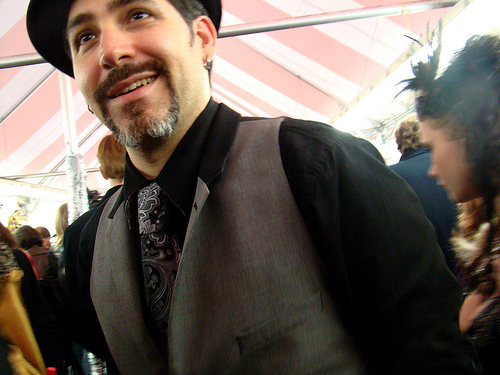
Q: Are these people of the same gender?
A: No, they are both male and female.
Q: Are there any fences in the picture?
A: No, there are no fences.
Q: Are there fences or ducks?
A: No, there are no fences or ducks.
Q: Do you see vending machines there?
A: No, there are no vending machines.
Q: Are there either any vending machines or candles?
A: No, there are no vending machines or candles.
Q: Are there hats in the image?
A: Yes, there is a hat.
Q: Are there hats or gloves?
A: Yes, there is a hat.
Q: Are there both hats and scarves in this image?
A: No, there is a hat but no scarves.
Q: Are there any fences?
A: No, there are no fences.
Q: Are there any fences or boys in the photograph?
A: No, there are no fences or boys.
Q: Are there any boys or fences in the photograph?
A: No, there are no fences or boys.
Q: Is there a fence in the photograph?
A: No, there are no fences.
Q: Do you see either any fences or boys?
A: No, there are no fences or boys.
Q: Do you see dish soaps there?
A: No, there are no dish soaps.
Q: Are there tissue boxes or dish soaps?
A: No, there are no dish soaps or tissue boxes.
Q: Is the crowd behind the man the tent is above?
A: Yes, the crowd is behind the man.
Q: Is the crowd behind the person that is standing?
A: Yes, the crowd is behind the man.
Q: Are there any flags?
A: No, there are no flags.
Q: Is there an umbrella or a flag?
A: No, there are no flags or umbrellas.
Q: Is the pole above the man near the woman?
A: Yes, the pole is above the man.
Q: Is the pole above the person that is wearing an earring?
A: Yes, the pole is above the man.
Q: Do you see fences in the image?
A: No, there are no fences.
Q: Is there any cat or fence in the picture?
A: No, there are no fences or cats.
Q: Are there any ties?
A: Yes, there is a tie.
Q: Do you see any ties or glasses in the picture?
A: Yes, there is a tie.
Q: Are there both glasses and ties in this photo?
A: No, there is a tie but no glasses.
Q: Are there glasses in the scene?
A: No, there are no glasses.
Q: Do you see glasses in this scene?
A: No, there are no glasses.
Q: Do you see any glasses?
A: No, there are no glasses.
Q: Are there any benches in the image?
A: No, there are no benches.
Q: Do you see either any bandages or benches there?
A: No, there are no benches or bandages.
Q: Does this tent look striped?
A: Yes, the tent is striped.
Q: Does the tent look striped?
A: Yes, the tent is striped.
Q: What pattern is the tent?
A: The tent is striped.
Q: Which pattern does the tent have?
A: The tent has striped pattern.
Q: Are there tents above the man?
A: Yes, there is a tent above the man.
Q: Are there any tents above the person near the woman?
A: Yes, there is a tent above the man.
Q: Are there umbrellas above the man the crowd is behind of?
A: No, there is a tent above the man.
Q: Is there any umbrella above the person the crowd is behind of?
A: No, there is a tent above the man.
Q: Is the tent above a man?
A: Yes, the tent is above a man.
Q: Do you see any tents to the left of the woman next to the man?
A: Yes, there is a tent to the left of the woman.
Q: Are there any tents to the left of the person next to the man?
A: Yes, there is a tent to the left of the woman.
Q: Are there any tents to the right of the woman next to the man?
A: No, the tent is to the left of the woman.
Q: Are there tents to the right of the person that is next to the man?
A: No, the tent is to the left of the woman.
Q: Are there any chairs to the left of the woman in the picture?
A: No, there is a tent to the left of the woman.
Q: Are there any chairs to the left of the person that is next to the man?
A: No, there is a tent to the left of the woman.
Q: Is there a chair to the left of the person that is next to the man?
A: No, there is a tent to the left of the woman.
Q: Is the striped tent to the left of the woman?
A: Yes, the tent is to the left of the woman.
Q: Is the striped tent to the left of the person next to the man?
A: Yes, the tent is to the left of the woman.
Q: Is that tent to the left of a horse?
A: No, the tent is to the left of the woman.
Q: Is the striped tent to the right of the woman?
A: No, the tent is to the left of the woman.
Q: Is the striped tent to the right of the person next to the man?
A: No, the tent is to the left of the woman.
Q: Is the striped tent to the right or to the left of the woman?
A: The tent is to the left of the woman.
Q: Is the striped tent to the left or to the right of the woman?
A: The tent is to the left of the woman.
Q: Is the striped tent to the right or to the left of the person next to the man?
A: The tent is to the left of the woman.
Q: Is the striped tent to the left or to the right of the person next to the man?
A: The tent is to the left of the woman.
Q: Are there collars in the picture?
A: Yes, there is a collar.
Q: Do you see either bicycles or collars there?
A: Yes, there is a collar.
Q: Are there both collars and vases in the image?
A: No, there is a collar but no vases.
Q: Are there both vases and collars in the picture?
A: No, there is a collar but no vases.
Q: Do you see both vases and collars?
A: No, there is a collar but no vases.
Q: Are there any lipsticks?
A: No, there are no lipsticks.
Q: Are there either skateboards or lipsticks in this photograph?
A: No, there are no lipsticks or skateboards.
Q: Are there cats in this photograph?
A: No, there are no cats.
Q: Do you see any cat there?
A: No, there are no cats.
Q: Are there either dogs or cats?
A: No, there are no cats or dogs.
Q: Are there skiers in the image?
A: No, there are no skiers.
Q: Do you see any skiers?
A: No, there are no skiers.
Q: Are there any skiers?
A: No, there are no skiers.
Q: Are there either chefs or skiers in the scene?
A: No, there are no skiers or chefs.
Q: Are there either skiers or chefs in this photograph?
A: No, there are no skiers or chefs.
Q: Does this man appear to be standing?
A: Yes, the man is standing.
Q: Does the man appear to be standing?
A: Yes, the man is standing.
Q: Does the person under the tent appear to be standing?
A: Yes, the man is standing.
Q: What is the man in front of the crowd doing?
A: The man is standing.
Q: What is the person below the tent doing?
A: The man is standing.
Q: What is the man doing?
A: The man is standing.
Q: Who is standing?
A: The man is standing.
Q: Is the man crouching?
A: No, the man is standing.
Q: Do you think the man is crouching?
A: No, the man is standing.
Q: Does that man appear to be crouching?
A: No, the man is standing.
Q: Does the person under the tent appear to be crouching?
A: No, the man is standing.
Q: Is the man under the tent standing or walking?
A: The man is standing.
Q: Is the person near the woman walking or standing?
A: The man is standing.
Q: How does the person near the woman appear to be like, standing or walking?
A: The man is standing.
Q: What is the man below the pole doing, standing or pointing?
A: The man is standing.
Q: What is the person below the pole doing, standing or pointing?
A: The man is standing.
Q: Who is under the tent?
A: The man is under the tent.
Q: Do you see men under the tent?
A: Yes, there is a man under the tent.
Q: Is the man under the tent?
A: Yes, the man is under the tent.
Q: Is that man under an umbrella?
A: No, the man is under the tent.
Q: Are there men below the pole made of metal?
A: Yes, there is a man below the pole.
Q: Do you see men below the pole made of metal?
A: Yes, there is a man below the pole.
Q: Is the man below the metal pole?
A: Yes, the man is below the pole.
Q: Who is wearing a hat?
A: The man is wearing a hat.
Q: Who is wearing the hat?
A: The man is wearing a hat.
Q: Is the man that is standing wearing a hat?
A: Yes, the man is wearing a hat.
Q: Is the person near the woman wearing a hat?
A: Yes, the man is wearing a hat.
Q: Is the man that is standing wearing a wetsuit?
A: No, the man is wearing a hat.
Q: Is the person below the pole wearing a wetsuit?
A: No, the man is wearing a hat.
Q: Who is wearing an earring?
A: The man is wearing an earring.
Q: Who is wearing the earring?
A: The man is wearing an earring.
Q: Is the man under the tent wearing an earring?
A: Yes, the man is wearing an earring.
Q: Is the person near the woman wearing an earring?
A: Yes, the man is wearing an earring.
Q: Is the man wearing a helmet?
A: No, the man is wearing an earring.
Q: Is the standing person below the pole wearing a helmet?
A: No, the man is wearing an earring.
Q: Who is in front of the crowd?
A: The man is in front of the crowd.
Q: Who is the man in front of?
A: The man is in front of the crowd.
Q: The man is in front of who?
A: The man is in front of the crowd.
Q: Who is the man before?
A: The man is in front of the crowd.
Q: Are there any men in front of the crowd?
A: Yes, there is a man in front of the crowd.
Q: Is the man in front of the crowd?
A: Yes, the man is in front of the crowd.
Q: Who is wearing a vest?
A: The man is wearing a vest.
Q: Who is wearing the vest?
A: The man is wearing a vest.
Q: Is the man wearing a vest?
A: Yes, the man is wearing a vest.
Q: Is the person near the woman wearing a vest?
A: Yes, the man is wearing a vest.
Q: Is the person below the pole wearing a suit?
A: No, the man is wearing a vest.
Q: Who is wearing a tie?
A: The man is wearing a tie.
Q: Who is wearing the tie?
A: The man is wearing a tie.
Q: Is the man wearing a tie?
A: Yes, the man is wearing a tie.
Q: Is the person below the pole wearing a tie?
A: Yes, the man is wearing a tie.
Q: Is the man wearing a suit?
A: No, the man is wearing a tie.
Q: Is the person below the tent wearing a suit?
A: No, the man is wearing a tie.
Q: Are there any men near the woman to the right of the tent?
A: Yes, there is a man near the woman.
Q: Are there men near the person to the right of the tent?
A: Yes, there is a man near the woman.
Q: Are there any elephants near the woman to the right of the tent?
A: No, there is a man near the woman.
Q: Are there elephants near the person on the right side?
A: No, there is a man near the woman.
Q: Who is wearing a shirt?
A: The man is wearing a shirt.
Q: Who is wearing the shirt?
A: The man is wearing a shirt.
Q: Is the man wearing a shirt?
A: Yes, the man is wearing a shirt.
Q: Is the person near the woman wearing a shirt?
A: Yes, the man is wearing a shirt.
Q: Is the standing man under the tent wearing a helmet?
A: No, the man is wearing a shirt.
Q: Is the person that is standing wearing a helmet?
A: No, the man is wearing a shirt.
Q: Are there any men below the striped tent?
A: Yes, there is a man below the tent.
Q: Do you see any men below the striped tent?
A: Yes, there is a man below the tent.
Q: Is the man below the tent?
A: Yes, the man is below the tent.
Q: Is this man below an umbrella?
A: No, the man is below the tent.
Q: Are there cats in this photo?
A: No, there are no cats.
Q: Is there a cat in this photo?
A: No, there are no cats.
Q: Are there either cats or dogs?
A: No, there are no cats or dogs.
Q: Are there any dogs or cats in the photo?
A: No, there are no cats or dogs.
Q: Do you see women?
A: Yes, there is a woman.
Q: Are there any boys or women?
A: Yes, there is a woman.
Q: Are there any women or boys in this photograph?
A: Yes, there is a woman.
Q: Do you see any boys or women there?
A: Yes, there is a woman.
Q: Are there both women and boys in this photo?
A: No, there is a woman but no boys.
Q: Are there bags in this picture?
A: No, there are no bags.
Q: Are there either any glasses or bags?
A: No, there are no bags or glasses.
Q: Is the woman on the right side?
A: Yes, the woman is on the right of the image.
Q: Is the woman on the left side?
A: No, the woman is on the right of the image.